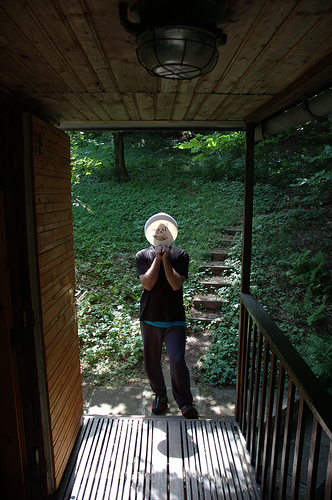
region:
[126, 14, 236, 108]
overhead light on porch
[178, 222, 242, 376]
steps coming down hill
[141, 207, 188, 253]
person holding Frisbee in front of face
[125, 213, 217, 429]
person standing at edge of porch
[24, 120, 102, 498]
wall on porch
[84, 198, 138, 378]
green ground covering growing on hillside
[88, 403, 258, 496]
floor to porch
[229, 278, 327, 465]
railing on porch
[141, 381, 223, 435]
adult tennis shoes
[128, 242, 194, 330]
adults black shirt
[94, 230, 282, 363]
grass is green and lush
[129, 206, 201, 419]
a boy playing with a frisbee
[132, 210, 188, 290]
the frisbee is being held by two hands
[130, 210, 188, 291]
a boy is holding the frisbee over his face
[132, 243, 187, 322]
the boy is wearing a black t-shirt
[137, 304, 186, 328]
a light blue t-shirt is underneath the black shirt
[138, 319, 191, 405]
blue jeans are being worn by the child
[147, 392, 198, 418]
the sneakers have an orange strupe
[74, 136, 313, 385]
a path behind the person is covered with greenery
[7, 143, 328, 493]
the building is made of wood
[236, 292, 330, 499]
a wood rail is on the porch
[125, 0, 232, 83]
A porch light on the ceiling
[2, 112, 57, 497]
Part of a doorway leading into building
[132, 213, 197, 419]
A man covering his face with a frisbee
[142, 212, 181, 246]
A white frisbee with colors on it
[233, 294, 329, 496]
A brown porch railing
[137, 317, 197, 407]
Navy blue sweat pants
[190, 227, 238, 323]
Cement steps going up a small hill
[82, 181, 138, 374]
A hillside of ivy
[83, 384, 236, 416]
A sidewalk that a man is standing on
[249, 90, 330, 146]
A rain gutter coming off the roof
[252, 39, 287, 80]
part of a wooden ceiling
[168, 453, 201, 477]
part of a wooden floor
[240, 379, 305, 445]
part of some wooden stands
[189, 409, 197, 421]
sole of a shoe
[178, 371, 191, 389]
part of a trouser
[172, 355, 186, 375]
part of a knee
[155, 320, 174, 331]
part of a t shirt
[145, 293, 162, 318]
part of a t shirt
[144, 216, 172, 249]
part of a dish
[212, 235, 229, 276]
part of a staircase